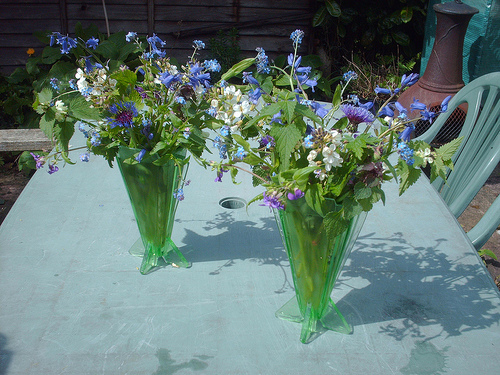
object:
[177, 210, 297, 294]
shadow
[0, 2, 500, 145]
garden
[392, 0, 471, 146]
fireplace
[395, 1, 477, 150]
heater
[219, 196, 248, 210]
hole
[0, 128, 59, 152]
wood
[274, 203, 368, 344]
vase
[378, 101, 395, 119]
blue flower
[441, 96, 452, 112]
blue flower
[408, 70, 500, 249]
chair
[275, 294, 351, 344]
feet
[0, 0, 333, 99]
fence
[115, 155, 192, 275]
vase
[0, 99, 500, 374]
bench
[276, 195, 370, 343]
vase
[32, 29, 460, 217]
blue flowers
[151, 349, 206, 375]
spot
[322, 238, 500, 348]
shadow